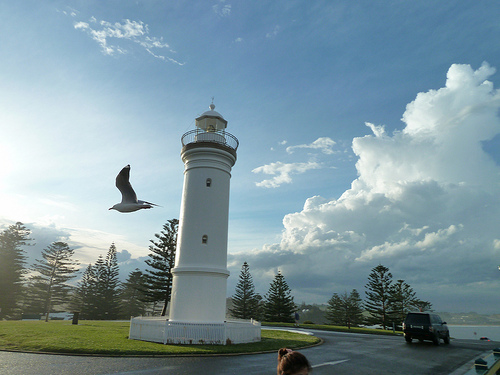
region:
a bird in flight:
[103, 163, 164, 218]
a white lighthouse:
[168, 88, 243, 347]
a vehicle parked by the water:
[396, 305, 456, 353]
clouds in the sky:
[343, 53, 494, 260]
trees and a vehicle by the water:
[357, 258, 454, 350]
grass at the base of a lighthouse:
[5, 310, 325, 357]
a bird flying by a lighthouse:
[104, 88, 267, 348]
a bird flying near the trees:
[73, 158, 168, 315]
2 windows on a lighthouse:
[193, 172, 220, 253]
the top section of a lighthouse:
[175, 93, 245, 174]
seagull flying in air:
[107, 163, 164, 214]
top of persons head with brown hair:
[274, 345, 310, 372]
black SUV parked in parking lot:
[401, 308, 452, 343]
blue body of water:
[366, 323, 498, 343]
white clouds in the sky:
[57, 8, 182, 66]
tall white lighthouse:
[127, 97, 264, 344]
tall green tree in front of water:
[366, 262, 396, 328]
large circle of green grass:
[0, 318, 322, 358]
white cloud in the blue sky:
[249, 161, 326, 188]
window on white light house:
[203, 234, 207, 244]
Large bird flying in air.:
[104, 164, 158, 222]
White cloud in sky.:
[253, 145, 308, 197]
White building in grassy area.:
[163, 172, 230, 321]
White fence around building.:
[128, 302, 193, 346]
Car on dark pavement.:
[396, 295, 448, 345]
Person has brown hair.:
[268, 345, 310, 372]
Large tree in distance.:
[263, 271, 309, 346]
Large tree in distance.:
[236, 265, 268, 315]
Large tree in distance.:
[361, 262, 394, 324]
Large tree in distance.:
[26, 250, 86, 324]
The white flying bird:
[104, 162, 161, 212]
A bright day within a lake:
[0, 0, 498, 373]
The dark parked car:
[404, 312, 451, 345]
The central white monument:
[129, 94, 262, 346]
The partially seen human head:
[274, 345, 316, 373]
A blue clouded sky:
[0, 0, 498, 314]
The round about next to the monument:
[0, 319, 498, 373]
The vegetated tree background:
[0, 219, 435, 325]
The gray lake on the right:
[351, 324, 498, 339]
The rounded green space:
[0, 319, 316, 354]